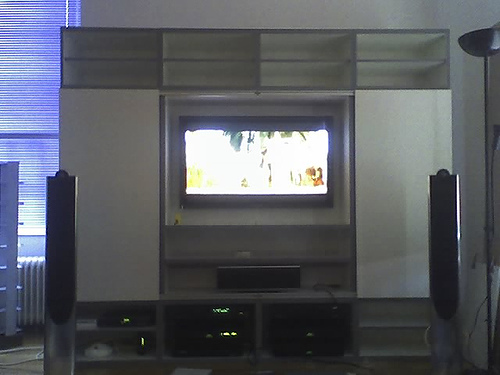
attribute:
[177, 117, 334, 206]
television — rectangular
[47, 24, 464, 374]
entertainment center — large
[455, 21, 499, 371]
lamp — tall, black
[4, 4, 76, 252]
window — large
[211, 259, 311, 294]
speaker — small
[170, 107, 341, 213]
television — on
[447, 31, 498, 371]
lamp — tall, black, a floor lamp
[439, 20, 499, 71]
shade — black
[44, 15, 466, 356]
center — large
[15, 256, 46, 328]
radiator — white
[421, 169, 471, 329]
speaker — tall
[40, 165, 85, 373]
speaker — large